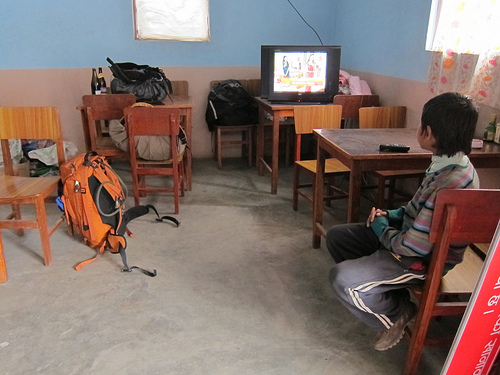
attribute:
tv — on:
[260, 43, 341, 104]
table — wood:
[253, 97, 369, 195]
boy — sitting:
[325, 92, 479, 349]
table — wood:
[312, 126, 498, 250]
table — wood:
[76, 91, 195, 193]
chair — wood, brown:
[122, 105, 184, 213]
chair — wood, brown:
[5, 108, 66, 268]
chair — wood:
[81, 91, 138, 174]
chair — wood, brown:
[292, 105, 351, 232]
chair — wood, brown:
[362, 102, 407, 137]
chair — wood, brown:
[401, 188, 494, 374]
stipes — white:
[347, 272, 427, 331]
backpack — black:
[104, 55, 174, 103]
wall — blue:
[6, 2, 337, 159]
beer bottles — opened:
[88, 65, 108, 95]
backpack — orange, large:
[62, 150, 162, 276]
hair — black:
[419, 93, 478, 162]